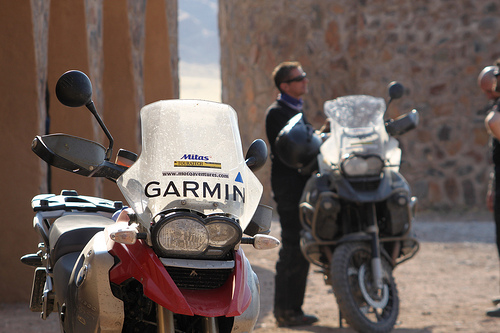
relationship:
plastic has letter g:
[114, 98, 265, 233] [138, 180, 161, 199]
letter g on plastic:
[138, 180, 161, 199] [114, 98, 265, 233]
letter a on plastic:
[158, 181, 180, 202] [114, 98, 265, 233]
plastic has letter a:
[114, 98, 265, 233] [158, 181, 180, 202]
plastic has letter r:
[114, 98, 265, 233] [178, 179, 201, 201]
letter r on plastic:
[178, 179, 201, 201] [114, 98, 265, 233]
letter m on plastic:
[200, 178, 225, 200] [114, 98, 265, 233]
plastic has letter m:
[114, 98, 265, 233] [200, 178, 225, 200]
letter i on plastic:
[220, 180, 235, 203] [114, 98, 265, 233]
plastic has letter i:
[114, 98, 265, 233] [220, 180, 235, 203]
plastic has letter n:
[114, 98, 265, 233] [233, 182, 249, 204]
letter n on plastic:
[233, 182, 249, 204] [114, 98, 265, 233]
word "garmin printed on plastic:
[136, 175, 261, 220] [113, 98, 265, 209]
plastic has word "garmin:
[113, 98, 265, 209] [136, 175, 261, 220]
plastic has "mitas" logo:
[113, 98, 265, 209] [171, 144, 228, 181]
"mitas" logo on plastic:
[171, 144, 228, 181] [113, 98, 265, 209]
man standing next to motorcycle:
[262, 61, 319, 327] [302, 75, 418, 330]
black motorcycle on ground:
[289, 99, 439, 331] [3, 197, 496, 327]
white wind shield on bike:
[113, 102, 263, 231] [20, 57, 290, 327]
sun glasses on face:
[280, 70, 310, 84] [287, 60, 311, 101]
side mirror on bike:
[23, 55, 139, 185] [20, 57, 290, 327]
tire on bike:
[327, 226, 408, 329] [289, 76, 424, 330]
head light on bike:
[196, 205, 247, 258] [20, 57, 290, 327]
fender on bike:
[104, 234, 272, 327] [20, 57, 290, 327]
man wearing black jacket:
[262, 61, 319, 327] [258, 93, 313, 211]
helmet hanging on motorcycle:
[276, 101, 321, 180] [291, 66, 422, 330]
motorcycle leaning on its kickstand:
[275, 69, 441, 330] [9, 66, 289, 333]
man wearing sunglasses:
[254, 53, 333, 327] [275, 66, 313, 87]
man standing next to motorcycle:
[262, 61, 319, 327] [291, 80, 438, 330]